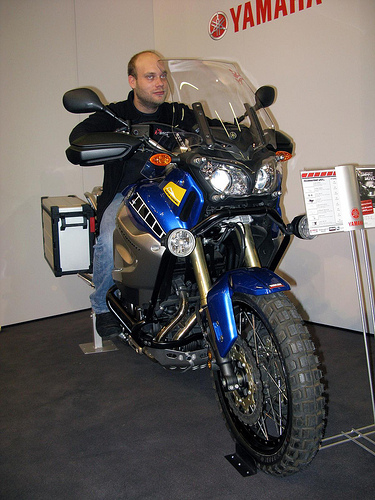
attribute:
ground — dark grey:
[0, 304, 374, 498]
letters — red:
[229, 0, 328, 33]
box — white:
[29, 185, 108, 283]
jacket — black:
[62, 89, 224, 238]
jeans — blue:
[103, 177, 145, 331]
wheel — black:
[206, 267, 334, 481]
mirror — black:
[253, 83, 277, 109]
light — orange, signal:
[144, 144, 179, 170]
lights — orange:
[193, 156, 247, 195]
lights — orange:
[253, 157, 277, 191]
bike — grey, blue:
[37, 87, 328, 479]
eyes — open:
[138, 68, 167, 83]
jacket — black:
[67, 88, 283, 201]